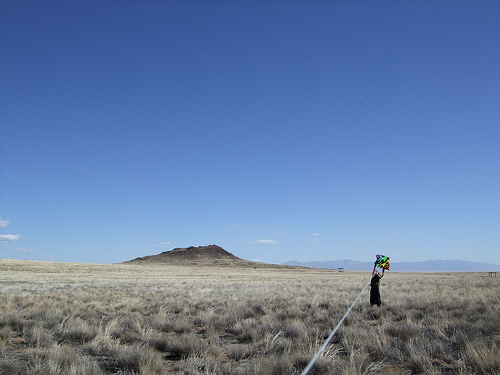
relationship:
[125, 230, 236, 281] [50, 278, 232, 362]
mountain on field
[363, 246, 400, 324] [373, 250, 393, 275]
person holding kite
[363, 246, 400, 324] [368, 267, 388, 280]
person with hands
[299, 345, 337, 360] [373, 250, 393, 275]
string of kite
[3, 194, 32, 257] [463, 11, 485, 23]
clouds in sky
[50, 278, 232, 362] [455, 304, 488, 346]
field has grass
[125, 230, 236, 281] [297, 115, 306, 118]
mountain in distance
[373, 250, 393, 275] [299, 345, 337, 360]
kite with string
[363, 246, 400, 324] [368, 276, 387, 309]
person in outfit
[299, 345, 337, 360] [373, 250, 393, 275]
string connected to kite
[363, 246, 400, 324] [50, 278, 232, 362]
person in field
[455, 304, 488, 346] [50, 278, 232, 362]
grass in field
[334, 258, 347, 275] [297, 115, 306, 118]
vehicle in distance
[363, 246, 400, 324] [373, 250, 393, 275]
person with kite